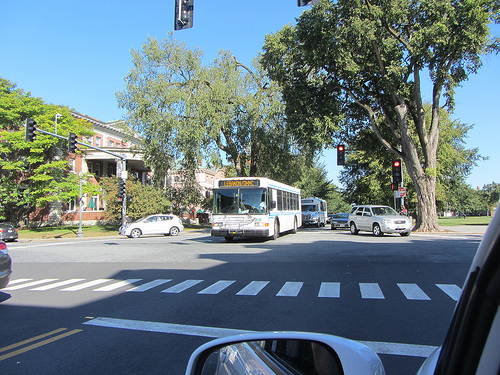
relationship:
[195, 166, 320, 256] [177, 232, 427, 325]
bus on road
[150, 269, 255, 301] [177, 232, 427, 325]
line on road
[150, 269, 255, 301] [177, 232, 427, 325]
line in road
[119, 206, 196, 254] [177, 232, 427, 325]
car on road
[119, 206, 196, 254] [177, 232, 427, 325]
car in road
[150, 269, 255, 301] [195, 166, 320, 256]
line near bus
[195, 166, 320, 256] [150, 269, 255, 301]
bus near line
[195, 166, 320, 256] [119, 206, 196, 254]
bus near car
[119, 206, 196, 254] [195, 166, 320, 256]
car near bus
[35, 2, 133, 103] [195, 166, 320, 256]
sky above bus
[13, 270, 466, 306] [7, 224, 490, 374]
lines in road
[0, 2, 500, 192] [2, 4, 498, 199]
sky with no clouds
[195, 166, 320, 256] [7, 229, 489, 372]
bus driving on road